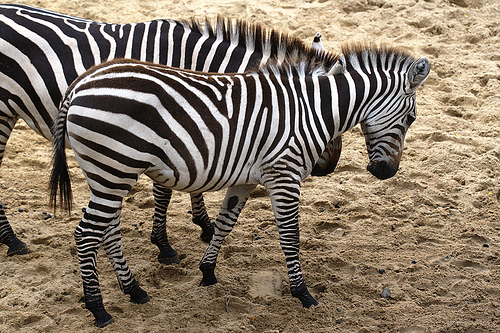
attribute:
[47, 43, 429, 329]
zebra — striped, looking, standing, black, close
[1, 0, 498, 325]
ground — sandy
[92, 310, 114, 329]
hoof — black